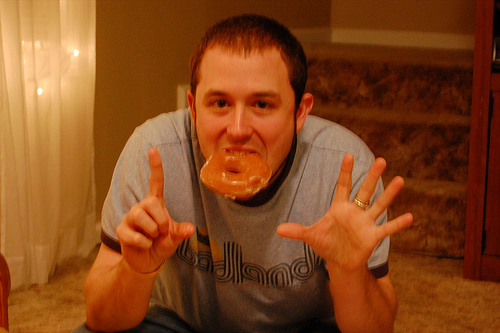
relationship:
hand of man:
[107, 138, 203, 276] [81, 16, 413, 328]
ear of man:
[183, 90, 202, 138] [187, 12, 313, 200]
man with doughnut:
[81, 16, 413, 328] [196, 146, 272, 207]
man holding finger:
[81, 16, 413, 328] [145, 144, 170, 203]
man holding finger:
[81, 16, 413, 328] [274, 217, 310, 243]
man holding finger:
[81, 16, 413, 328] [330, 148, 355, 207]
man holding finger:
[81, 16, 413, 328] [351, 155, 386, 213]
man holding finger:
[81, 16, 413, 328] [365, 170, 407, 223]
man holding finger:
[81, 16, 413, 328] [377, 209, 416, 237]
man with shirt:
[81, 16, 413, 328] [90, 101, 395, 330]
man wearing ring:
[81, 16, 413, 328] [352, 192, 369, 209]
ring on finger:
[352, 192, 369, 209] [351, 155, 386, 213]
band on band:
[121, 257, 167, 275] [121, 257, 167, 275]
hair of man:
[179, 8, 308, 108] [81, 16, 413, 328]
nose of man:
[226, 105, 257, 145] [81, 16, 413, 328]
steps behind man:
[276, 32, 478, 277] [81, 16, 413, 328]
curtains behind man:
[1, 1, 102, 289] [81, 16, 413, 328]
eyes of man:
[250, 95, 275, 114] [81, 16, 413, 328]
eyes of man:
[207, 95, 232, 115] [81, 16, 413, 328]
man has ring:
[81, 16, 413, 328] [352, 192, 369, 209]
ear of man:
[294, 90, 316, 134] [81, 16, 413, 328]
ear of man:
[183, 90, 202, 138] [81, 16, 413, 328]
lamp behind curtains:
[20, 30, 86, 105] [1, 1, 102, 289]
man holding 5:
[81, 16, 413, 328] [271, 150, 418, 277]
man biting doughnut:
[81, 16, 413, 328] [196, 146, 272, 207]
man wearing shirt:
[81, 16, 413, 328] [90, 101, 395, 330]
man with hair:
[81, 16, 413, 328] [179, 8, 308, 108]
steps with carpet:
[276, 32, 478, 277] [5, 215, 497, 332]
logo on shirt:
[172, 221, 330, 289] [90, 101, 395, 330]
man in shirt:
[81, 16, 413, 328] [90, 101, 395, 330]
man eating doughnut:
[81, 16, 413, 328] [196, 146, 272, 207]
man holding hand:
[81, 16, 413, 328] [107, 138, 203, 276]